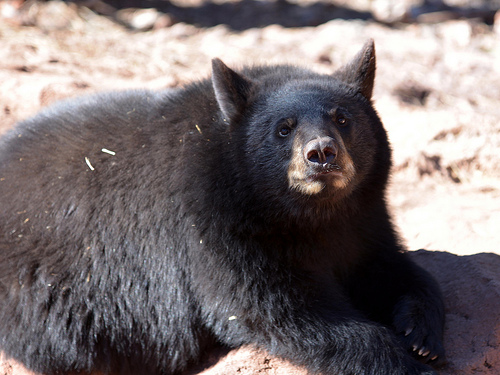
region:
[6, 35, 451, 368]
This is a bear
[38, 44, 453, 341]
a big black bear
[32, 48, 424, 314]
the bear is furry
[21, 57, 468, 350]
the bear looks relaxed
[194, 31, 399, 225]
the bear has pointy ears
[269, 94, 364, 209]
the bear has a calm look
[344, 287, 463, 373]
the bear's paws are black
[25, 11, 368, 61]
dirty ground beneath the bear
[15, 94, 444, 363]
the bear is in the dirt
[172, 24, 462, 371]
this bear is in the wild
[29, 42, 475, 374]
this bear is young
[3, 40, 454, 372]
a small black beaver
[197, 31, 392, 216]
head of a beaver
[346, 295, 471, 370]
paws of a beaver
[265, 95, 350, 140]
eyes of a beaver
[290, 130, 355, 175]
nose of a beaver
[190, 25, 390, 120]
ears of a beaver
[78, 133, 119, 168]
stuff on the fur of the animal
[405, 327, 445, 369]
claws of an animal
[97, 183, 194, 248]
furs of an animal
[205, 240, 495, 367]
a rocky platform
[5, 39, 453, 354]
large brown and black bear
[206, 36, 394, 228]
bear looking at camera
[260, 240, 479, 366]
bear resting it's paws on a rock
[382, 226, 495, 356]
shadow of bear on rock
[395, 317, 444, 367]
bears nails on it's paw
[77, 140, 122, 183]
pieces of dirt on bear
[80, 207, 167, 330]
black fur on bear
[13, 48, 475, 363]
photograph taken in a zoo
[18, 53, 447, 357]
photo of a bear in a zoo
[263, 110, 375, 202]
light brown fur around bears nose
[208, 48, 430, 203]
The bear is staring at the camera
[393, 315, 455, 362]
The bear's claws are out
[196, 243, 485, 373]
The bear is resting on a boulder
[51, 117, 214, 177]
The bear has debris on it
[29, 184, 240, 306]
The bear has thick black fur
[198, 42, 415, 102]
The bear's ears are shaped like traingles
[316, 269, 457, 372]
The bear's front left paw is on top of its front right paw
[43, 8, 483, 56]
The area is mostly covered in rock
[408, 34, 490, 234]
The sun is reflecting on the rocks